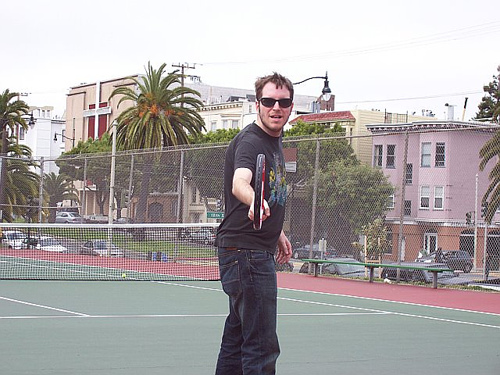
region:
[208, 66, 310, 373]
man on a tennis court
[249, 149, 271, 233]
tennis racket in a man's hand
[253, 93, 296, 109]
sunglasses on a man's face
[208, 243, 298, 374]
man's blue jeans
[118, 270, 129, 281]
yellow ball on a tennis court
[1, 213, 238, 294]
net on the tennis court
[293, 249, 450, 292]
green bench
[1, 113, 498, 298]
fence surrounding the court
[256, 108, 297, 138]
facial hair on the man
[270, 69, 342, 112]
tall black lamp post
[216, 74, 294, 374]
man standing in a tennis court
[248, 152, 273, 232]
man holding a tennis racket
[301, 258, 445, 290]
a green bench on a tennis court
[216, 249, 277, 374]
man wearing black jeans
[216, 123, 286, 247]
man wearing a black T-shirt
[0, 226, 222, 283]
a tennis net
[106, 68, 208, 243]
a palm tree outside a tennis court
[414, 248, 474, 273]
a brown car in the street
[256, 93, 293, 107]
man wearing black sunglasses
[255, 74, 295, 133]
man with short brown hair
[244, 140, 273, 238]
the frisbee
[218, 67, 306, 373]
a man wearing sunglasses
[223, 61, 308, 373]
a man throwing a frisbee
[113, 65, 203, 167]
a palm tree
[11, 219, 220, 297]
a net of a tennis court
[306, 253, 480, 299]
a green bench on the side of the tennis court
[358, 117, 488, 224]
a pink home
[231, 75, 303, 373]
a man wearing black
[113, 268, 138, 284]
a tennis ball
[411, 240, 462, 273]
people getting in their car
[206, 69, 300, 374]
man holding tennis racket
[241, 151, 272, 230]
tennis racket in right hand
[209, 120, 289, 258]
man wearing black shirt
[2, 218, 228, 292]
net stretched across tennis court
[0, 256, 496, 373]
tennis court is green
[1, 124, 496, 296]
fence as a barrier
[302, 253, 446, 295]
bench sitting against the fence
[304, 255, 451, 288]
bench on court sidelines is green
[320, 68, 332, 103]
lamppost haning from pole